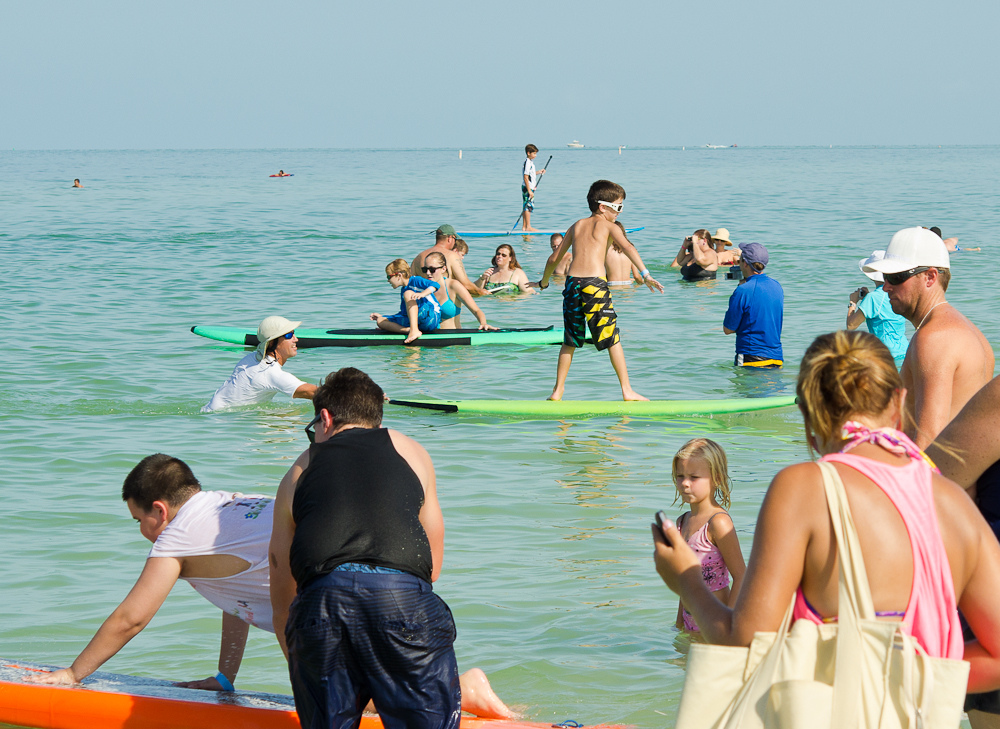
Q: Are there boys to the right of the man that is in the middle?
A: Yes, there is a boy to the right of the man.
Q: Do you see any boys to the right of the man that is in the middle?
A: Yes, there is a boy to the right of the man.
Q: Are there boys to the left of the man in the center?
A: No, the boy is to the right of the man.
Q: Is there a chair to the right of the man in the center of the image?
A: No, there is a boy to the right of the man.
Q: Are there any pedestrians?
A: No, there are no pedestrians.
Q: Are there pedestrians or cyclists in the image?
A: No, there are no pedestrians or cyclists.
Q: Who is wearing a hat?
A: The man is wearing a hat.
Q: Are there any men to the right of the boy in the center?
A: Yes, there is a man to the right of the boy.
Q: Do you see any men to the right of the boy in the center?
A: Yes, there is a man to the right of the boy.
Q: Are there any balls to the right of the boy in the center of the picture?
A: No, there is a man to the right of the boy.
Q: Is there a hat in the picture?
A: Yes, there is a hat.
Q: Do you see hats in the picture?
A: Yes, there is a hat.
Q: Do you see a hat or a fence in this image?
A: Yes, there is a hat.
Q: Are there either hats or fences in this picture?
A: Yes, there is a hat.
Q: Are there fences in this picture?
A: No, there are no fences.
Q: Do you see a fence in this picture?
A: No, there are no fences.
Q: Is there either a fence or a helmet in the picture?
A: No, there are no fences or helmets.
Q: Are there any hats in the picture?
A: Yes, there is a hat.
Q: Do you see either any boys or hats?
A: Yes, there is a hat.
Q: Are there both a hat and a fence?
A: No, there is a hat but no fences.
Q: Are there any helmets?
A: No, there are no helmets.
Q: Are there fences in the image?
A: No, there are no fences.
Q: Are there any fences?
A: No, there are no fences.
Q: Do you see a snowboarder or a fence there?
A: No, there are no fences or snowboarders.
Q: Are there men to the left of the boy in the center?
A: Yes, there is a man to the left of the boy.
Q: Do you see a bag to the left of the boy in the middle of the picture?
A: No, there is a man to the left of the boy.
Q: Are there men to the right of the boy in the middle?
A: Yes, there is a man to the right of the boy.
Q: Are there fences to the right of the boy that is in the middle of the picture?
A: No, there is a man to the right of the boy.